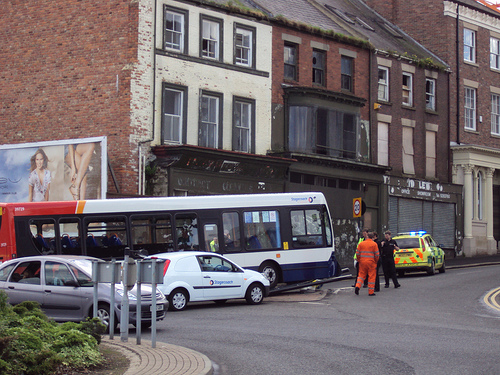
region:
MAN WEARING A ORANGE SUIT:
[359, 241, 371, 293]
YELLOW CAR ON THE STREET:
[393, 229, 446, 272]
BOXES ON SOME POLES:
[93, 259, 165, 278]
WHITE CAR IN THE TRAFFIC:
[168, 249, 268, 314]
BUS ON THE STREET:
[2, 199, 321, 256]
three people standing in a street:
[351, 225, 402, 300]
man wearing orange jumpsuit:
[348, 230, 385, 296]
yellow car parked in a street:
[388, 228, 453, 274]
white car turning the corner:
[127, 245, 274, 312]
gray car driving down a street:
[0, 252, 167, 329]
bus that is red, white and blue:
[3, 190, 350, 292]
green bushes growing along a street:
[0, 299, 109, 374]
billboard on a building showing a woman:
[0, 135, 111, 201]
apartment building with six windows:
[0, 0, 275, 200]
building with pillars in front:
[445, 0, 498, 263]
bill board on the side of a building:
[0, 136, 110, 202]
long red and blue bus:
[2, 192, 337, 288]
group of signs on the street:
[87, 256, 164, 348]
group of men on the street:
[352, 231, 401, 298]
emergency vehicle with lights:
[387, 230, 447, 275]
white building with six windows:
[136, 2, 271, 157]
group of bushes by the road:
[0, 291, 104, 373]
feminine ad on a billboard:
[3, 136, 106, 205]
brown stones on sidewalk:
[96, 332, 211, 372]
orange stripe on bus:
[77, 200, 86, 215]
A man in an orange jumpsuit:
[350, 228, 380, 295]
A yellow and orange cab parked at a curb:
[387, 227, 443, 267]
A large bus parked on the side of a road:
[5, 191, 337, 292]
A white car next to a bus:
[122, 250, 268, 305]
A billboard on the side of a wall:
[5, 135, 110, 241]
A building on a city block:
[125, 130, 495, 290]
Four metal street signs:
[90, 255, 160, 345]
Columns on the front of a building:
[455, 150, 495, 255]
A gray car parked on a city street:
[0, 251, 167, 334]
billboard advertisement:
[1, 133, 109, 204]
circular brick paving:
[96, 332, 214, 374]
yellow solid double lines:
[480, 282, 499, 313]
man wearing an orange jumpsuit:
[352, 228, 382, 298]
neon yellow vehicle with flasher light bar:
[390, 228, 447, 278]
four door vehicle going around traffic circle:
[1, 251, 172, 333]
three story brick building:
[2, 0, 468, 265]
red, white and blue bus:
[1, 190, 337, 292]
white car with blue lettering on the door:
[128, 247, 272, 310]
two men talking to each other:
[351, 227, 402, 298]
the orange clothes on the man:
[354, 232, 380, 297]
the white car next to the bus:
[143, 248, 272, 310]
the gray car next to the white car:
[0, 255, 166, 332]